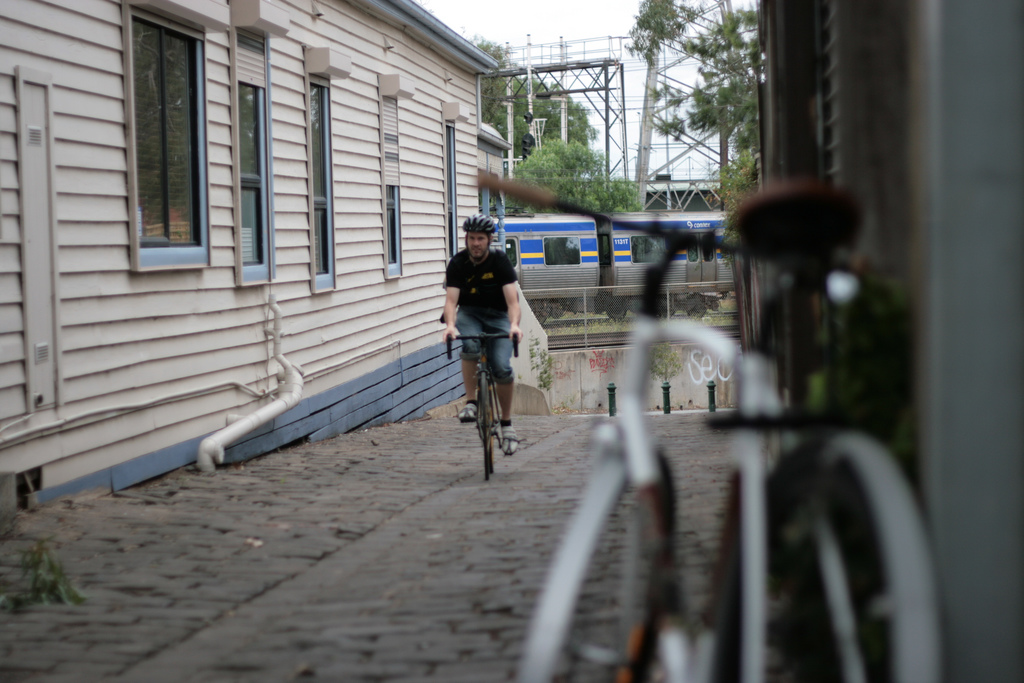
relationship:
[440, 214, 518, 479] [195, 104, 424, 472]
man riding a bike between building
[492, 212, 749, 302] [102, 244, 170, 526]
train behind building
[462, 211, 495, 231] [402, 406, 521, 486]
helmet on a man riding a bike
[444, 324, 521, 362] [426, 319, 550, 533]
handlebars has two hands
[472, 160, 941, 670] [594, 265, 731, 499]
bike closest to cameral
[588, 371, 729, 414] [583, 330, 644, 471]
poles in ground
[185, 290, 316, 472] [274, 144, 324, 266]
pipe on side of a building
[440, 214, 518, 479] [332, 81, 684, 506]
man on a bike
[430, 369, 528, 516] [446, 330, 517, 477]
front tire of a bicycle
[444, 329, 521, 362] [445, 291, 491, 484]
handlebars on bike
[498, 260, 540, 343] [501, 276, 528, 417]
arm of man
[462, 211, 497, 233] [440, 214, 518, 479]
helmet on man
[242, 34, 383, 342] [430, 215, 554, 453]
window next to man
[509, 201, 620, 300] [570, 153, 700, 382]
window on train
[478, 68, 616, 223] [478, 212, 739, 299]
trees near train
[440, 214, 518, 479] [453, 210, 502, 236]
man riding with a helmet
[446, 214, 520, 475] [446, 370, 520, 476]
man riding a bicycle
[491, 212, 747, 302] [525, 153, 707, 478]
train in background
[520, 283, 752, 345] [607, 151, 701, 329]
fence to keep off tracks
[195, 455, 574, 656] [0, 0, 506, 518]
bricks walk between building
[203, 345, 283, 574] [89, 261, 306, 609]
water spout on side of house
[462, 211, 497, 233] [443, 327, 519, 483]
helmet on mans head riding bike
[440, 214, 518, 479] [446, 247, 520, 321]
man wearing shirt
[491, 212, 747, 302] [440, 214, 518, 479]
train behind man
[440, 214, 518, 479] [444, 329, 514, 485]
man on bike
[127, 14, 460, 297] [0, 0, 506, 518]
windows on building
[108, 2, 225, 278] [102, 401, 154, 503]
window on left of building